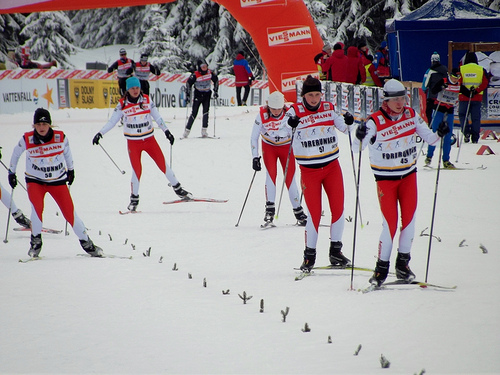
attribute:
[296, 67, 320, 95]
beanie — black, light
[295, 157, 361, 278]
pants — red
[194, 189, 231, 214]
ski — red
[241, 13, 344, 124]
sign — red, white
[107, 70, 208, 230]
competitor — here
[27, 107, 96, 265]
uniform — here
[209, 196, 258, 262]
snow — white, diffuse, here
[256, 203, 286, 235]
foot — here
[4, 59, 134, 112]
barrier — here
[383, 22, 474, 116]
tent — blue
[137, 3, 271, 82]
tree — here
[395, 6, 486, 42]
roof — here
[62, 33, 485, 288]
people — skiing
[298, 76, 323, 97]
hat — black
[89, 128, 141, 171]
pole — skinny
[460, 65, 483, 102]
vest — yellow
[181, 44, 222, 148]
skier — cross country , here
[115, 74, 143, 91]
cap — blue